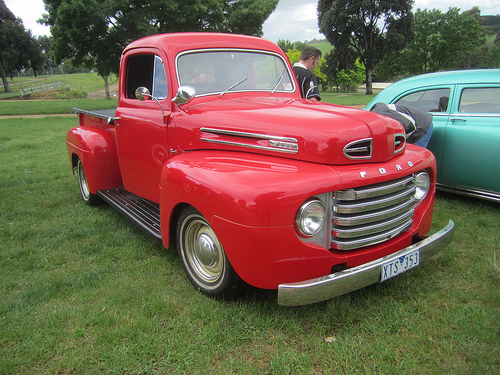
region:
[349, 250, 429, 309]
white and blue license plate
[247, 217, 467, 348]
silver front bumper of truck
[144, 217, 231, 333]
black tire with silver rim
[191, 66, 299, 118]
two wind shield wipers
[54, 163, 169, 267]
foot step up on a truck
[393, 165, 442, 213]
head light on front of truck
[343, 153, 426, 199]
a silver ford sign on truck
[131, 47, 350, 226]
man standing by a truck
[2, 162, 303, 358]
truck parked on grass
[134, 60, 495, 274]
red and green truck and car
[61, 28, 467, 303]
antique red Ford pickup truck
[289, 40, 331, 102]
man standing next to truck looking downward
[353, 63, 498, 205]
right rear side of antique vehicle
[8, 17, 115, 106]
picturesque country with dirt road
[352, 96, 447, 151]
man bending over between old red ford pickup and antique car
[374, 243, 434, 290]
license plate with blue letters on white background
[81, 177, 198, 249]
wide, black running board on antique Ford truck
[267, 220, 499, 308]
chrome bumper on Ford truck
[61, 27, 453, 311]
shiny, cherry red old pickup truck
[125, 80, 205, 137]
double mirrors on passenger side of antique truck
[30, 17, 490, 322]
antique cars in a field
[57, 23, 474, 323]
a red Ford pick-up truck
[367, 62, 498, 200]
an antique green car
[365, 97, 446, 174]
a person bending over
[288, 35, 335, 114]
man leaning against the truck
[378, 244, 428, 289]
the truck's lisence plate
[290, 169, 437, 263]
the truck's headlights and grill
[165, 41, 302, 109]
the truck's front windsheild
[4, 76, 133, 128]
a dirt road in the distance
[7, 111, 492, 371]
a green grassy field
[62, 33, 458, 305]
classic red pickup truck on grass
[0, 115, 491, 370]
green grassy field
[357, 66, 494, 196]
classic green car next to classic truck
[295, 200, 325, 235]
headlight on classic truck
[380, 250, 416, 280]
white license plate on bumper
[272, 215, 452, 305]
chrome bumper on truck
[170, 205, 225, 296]
black tire on truck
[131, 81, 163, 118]
chrome rearview mirror on truck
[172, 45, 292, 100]
glass windshield on truck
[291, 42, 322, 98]
man standing next to truck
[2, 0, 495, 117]
a row green trees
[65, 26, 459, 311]
an old fashion red truck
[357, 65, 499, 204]
a blue car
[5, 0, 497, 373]
a scene outside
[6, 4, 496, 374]
a scene happening during the day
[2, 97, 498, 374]
a green field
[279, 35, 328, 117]
a man next to the red truck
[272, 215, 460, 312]
a silver bumper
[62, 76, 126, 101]
a road in the background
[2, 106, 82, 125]
a tan trail